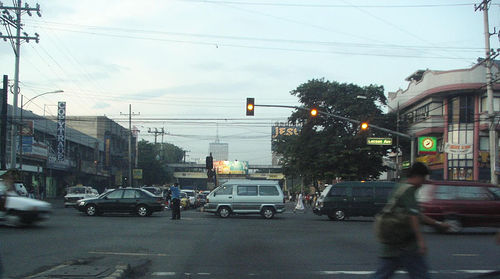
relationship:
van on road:
[201, 180, 287, 219] [0, 194, 500, 279]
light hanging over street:
[243, 97, 260, 113] [5, 195, 480, 270]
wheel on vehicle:
[85, 203, 98, 212] [69, 187, 168, 216]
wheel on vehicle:
[139, 204, 149, 217] [69, 187, 168, 216]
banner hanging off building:
[441, 142, 473, 154] [386, 61, 483, 204]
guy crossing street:
[370, 161, 449, 279] [20, 184, 484, 267]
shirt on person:
[378, 184, 422, 239] [374, 160, 448, 276]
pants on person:
[373, 239, 432, 277] [374, 160, 448, 276]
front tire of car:
[218, 206, 232, 218] [202, 178, 284, 219]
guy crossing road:
[370, 161, 449, 279] [40, 197, 484, 273]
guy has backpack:
[370, 161, 449, 279] [370, 205, 403, 246]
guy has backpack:
[370, 161, 436, 275] [365, 210, 408, 246]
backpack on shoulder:
[365, 210, 408, 246] [400, 178, 428, 199]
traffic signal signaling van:
[240, 92, 324, 133] [201, 180, 287, 219]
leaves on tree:
[306, 84, 337, 109] [289, 81, 395, 210]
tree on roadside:
[273, 77, 395, 185] [267, 188, 368, 229]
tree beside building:
[291, 79, 387, 185] [388, 62, 496, 191]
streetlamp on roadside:
[12, 82, 65, 133] [11, 150, 80, 221]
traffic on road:
[4, 172, 461, 206] [6, 212, 434, 275]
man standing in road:
[164, 182, 181, 220] [83, 213, 329, 275]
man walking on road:
[292, 190, 306, 213] [71, 212, 394, 267]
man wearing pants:
[292, 190, 306, 213] [368, 244, 432, 279]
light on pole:
[246, 98, 255, 116] [253, 100, 365, 130]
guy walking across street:
[370, 161, 449, 279] [82, 213, 373, 267]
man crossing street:
[164, 182, 191, 220] [85, 216, 384, 273]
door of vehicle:
[209, 185, 233, 209] [200, 170, 288, 221]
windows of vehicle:
[235, 181, 282, 200] [198, 173, 293, 216]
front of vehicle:
[200, 170, 235, 216] [195, 167, 292, 219]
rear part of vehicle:
[252, 173, 286, 221] [202, 168, 294, 228]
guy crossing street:
[370, 161, 449, 279] [63, 213, 486, 273]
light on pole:
[246, 98, 255, 116] [233, 85, 423, 169]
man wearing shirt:
[164, 182, 181, 220] [164, 184, 183, 197]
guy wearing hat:
[370, 161, 449, 279] [396, 149, 431, 178]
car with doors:
[71, 178, 169, 221] [101, 200, 140, 211]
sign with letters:
[45, 89, 72, 170] [59, 105, 64, 150]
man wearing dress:
[292, 190, 306, 213] [292, 197, 301, 217]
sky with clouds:
[22, 23, 460, 149] [173, 15, 259, 132]